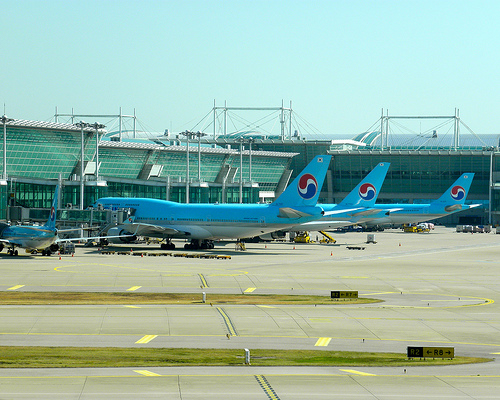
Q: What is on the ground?
A: Airplanes.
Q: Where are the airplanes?
A: At the airport.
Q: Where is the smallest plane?
A: On the left.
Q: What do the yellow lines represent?
A: The landing strip.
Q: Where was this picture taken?
A: An airport.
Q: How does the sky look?
A: Blue and clear.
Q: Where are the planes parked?
A: At the gates.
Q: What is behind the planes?
A: The terminal.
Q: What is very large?
A: The planes.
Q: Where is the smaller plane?
A: To the left of the larger planes.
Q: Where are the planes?
A: Parked at the airport.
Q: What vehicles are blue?
A: The planes.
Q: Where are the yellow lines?
A: On the pavement.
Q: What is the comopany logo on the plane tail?
A: Pepsi.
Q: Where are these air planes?
A: Airport.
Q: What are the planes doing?
A: Parked.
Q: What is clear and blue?
A: Sky.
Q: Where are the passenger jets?
A: Airport.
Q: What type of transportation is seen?
A: Jets.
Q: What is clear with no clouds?
A: Sky.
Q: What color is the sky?
A: Blue.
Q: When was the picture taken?
A: Daytime.